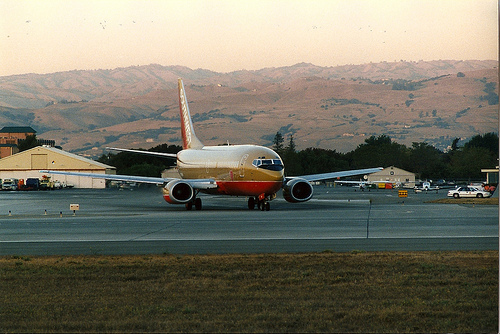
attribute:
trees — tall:
[358, 138, 495, 174]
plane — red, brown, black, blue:
[42, 79, 384, 210]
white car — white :
[448, 182, 493, 200]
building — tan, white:
[2, 143, 115, 188]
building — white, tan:
[362, 167, 417, 186]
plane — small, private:
[37, 64, 425, 294]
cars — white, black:
[424, 153, 497, 209]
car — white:
[448, 182, 491, 200]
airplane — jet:
[39, 55, 437, 212]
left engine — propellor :
[281, 177, 318, 201]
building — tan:
[357, 161, 421, 190]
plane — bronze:
[41, 90, 409, 227]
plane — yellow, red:
[157, 79, 314, 194]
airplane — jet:
[42, 76, 382, 210]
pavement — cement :
[0, 177, 500, 253]